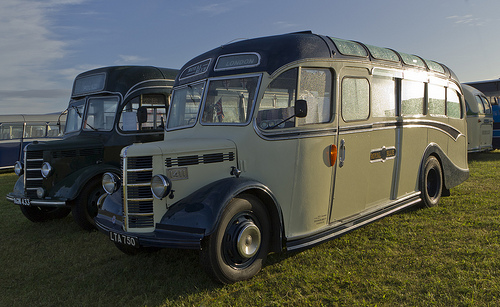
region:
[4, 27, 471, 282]
two old fashion vehicles parked on a grassy field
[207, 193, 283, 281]
black wheel of a vintage vehicle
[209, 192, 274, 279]
front wheel of a vintage vehicle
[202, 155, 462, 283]
two wheels on a vintage vehicle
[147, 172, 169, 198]
round white head light on the front of a vintage vehicle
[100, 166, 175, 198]
two round car lights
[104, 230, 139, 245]
white and black front license plate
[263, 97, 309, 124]
rearview mirror of a vintage vehicle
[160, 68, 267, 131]
windshield of a vintage vehicle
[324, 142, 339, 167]
orange light on a vintage vehicle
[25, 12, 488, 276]
two buses in the grass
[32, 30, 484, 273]
these ae busses from a different era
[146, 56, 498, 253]
this bus is light green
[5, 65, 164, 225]
this is a dark green bus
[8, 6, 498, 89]
the sky is shining bright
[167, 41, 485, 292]
the sun is shining on the bus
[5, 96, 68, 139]
the area behind the bus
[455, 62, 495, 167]
a bus in the background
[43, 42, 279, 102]
windows on the top part of the bus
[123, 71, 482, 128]
windows on the buses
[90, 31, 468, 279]
a light green bus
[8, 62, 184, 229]
a black bus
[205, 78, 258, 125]
a bus front windshield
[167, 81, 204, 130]
a bus front windshield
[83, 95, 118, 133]
a bus front windshield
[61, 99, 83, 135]
a bus front windshield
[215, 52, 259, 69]
a bus destination sign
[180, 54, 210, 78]
a bus destination sign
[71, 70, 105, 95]
a bus destination sign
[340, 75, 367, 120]
a bus side passenger window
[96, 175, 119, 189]
The left headlight on the beige car.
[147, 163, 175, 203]
The right headlight on the beige car.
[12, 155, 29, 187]
The left headlight on the black car.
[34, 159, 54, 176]
The right headlight on the black car.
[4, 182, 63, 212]
The front fender of the black car.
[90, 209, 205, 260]
The front fender of the beige car.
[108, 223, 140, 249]
The license plate of the beige car.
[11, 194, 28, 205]
The license plate on the black car.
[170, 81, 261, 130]
The front windows on the beige car.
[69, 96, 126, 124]
The front windows of the black car.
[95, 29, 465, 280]
the car is olive green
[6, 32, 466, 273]
two large vehicles parked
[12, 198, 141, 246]
two vehicles have license plates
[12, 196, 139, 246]
license plates have numbers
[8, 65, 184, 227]
the vehicle is black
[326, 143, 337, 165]
the vehicle has a red light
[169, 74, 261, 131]
the front windows are small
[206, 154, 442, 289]
the wheels are black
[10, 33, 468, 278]
the two vehicles are parked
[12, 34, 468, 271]
the vehicles are retro